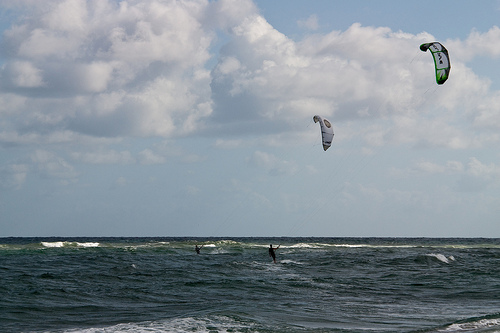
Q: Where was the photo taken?
A: It was taken at the ocean.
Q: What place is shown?
A: It is an ocean.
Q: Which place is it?
A: It is an ocean.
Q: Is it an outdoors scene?
A: Yes, it is outdoors.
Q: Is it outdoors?
A: Yes, it is outdoors.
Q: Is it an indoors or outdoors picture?
A: It is outdoors.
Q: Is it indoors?
A: No, it is outdoors.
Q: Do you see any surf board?
A: No, there are no surfboards.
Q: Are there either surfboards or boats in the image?
A: No, there are no surfboards or boats.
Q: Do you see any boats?
A: No, there are no boats.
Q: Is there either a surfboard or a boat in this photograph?
A: No, there are no boats or surfboards.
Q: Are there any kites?
A: Yes, there is a kite.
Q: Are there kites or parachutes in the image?
A: Yes, there is a kite.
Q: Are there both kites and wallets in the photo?
A: No, there is a kite but no wallets.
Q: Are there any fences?
A: No, there are no fences.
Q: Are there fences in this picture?
A: No, there are no fences.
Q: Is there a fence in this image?
A: No, there are no fences.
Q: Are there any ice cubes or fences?
A: No, there are no fences or ice cubes.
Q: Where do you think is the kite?
A: The kite is in the sky.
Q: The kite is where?
A: The kite is in the sky.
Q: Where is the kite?
A: The kite is in the sky.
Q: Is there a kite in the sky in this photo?
A: Yes, there is a kite in the sky.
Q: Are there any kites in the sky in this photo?
A: Yes, there is a kite in the sky.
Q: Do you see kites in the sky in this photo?
A: Yes, there is a kite in the sky.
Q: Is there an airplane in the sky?
A: No, there is a kite in the sky.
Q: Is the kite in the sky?
A: Yes, the kite is in the sky.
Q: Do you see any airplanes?
A: No, there are no airplanes.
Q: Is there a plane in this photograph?
A: No, there are no airplanes.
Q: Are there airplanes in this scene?
A: No, there are no airplanes.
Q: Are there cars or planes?
A: No, there are no planes or cars.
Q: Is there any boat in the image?
A: No, there are no boats.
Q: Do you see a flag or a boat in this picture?
A: No, there are no boats or flags.